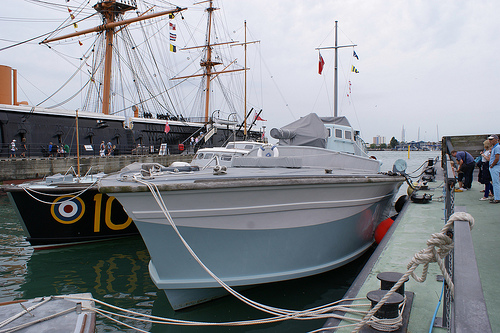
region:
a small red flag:
[311, 46, 337, 76]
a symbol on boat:
[43, 188, 90, 227]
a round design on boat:
[41, 193, 93, 228]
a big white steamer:
[61, 132, 392, 328]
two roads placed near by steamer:
[348, 254, 424, 314]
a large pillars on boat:
[72, 0, 184, 158]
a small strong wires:
[108, 12, 199, 119]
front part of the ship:
[110, 170, 240, 312]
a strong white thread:
[128, 179, 318, 328]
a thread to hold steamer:
[167, 208, 407, 331]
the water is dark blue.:
[13, 231, 134, 296]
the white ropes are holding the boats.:
[0, 180, 480, 330]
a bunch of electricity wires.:
[11, 60, 276, 125]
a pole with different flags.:
[310, 15, 360, 100]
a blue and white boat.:
[100, 120, 435, 315]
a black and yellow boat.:
[1, 165, 141, 245]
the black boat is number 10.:
[85, 185, 130, 235]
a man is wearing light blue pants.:
[490, 160, 495, 195]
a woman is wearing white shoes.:
[475, 186, 491, 206]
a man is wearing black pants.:
[461, 158, 472, 188]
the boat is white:
[212, 50, 356, 325]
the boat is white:
[283, 135, 355, 330]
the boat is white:
[225, 72, 300, 317]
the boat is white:
[178, 0, 286, 316]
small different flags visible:
[166, 13, 181, 60]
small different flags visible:
[160, 11, 190, 59]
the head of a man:
[448, 144, 460, 159]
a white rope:
[342, 202, 479, 331]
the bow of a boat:
[93, 152, 204, 318]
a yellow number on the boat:
[86, 190, 136, 235]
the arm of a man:
[454, 152, 465, 169]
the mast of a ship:
[166, 4, 241, 153]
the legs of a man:
[458, 160, 478, 187]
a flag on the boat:
[313, 48, 333, 77]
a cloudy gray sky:
[0, 0, 499, 142]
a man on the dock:
[448, 144, 479, 193]